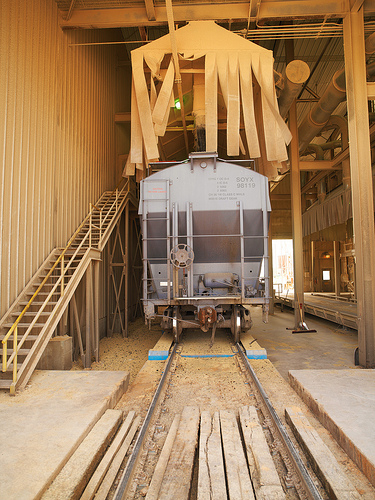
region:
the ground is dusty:
[27, 342, 120, 465]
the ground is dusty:
[8, 334, 160, 496]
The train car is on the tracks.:
[117, 150, 284, 355]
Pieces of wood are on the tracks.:
[64, 390, 336, 498]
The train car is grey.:
[126, 146, 288, 350]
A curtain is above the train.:
[109, 17, 300, 197]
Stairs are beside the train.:
[0, 174, 138, 399]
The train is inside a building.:
[0, 4, 374, 497]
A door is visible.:
[261, 225, 304, 319]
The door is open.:
[263, 232, 303, 317]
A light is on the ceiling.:
[163, 82, 197, 117]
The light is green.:
[160, 84, 193, 120]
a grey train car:
[133, 151, 274, 348]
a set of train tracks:
[99, 317, 343, 498]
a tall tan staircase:
[0, 173, 145, 396]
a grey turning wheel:
[167, 238, 195, 272]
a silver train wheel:
[227, 307, 242, 343]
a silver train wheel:
[170, 306, 180, 342]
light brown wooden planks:
[149, 403, 284, 497]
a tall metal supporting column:
[283, 98, 310, 336]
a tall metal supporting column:
[345, 12, 371, 369]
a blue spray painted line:
[144, 346, 266, 363]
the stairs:
[8, 150, 123, 393]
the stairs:
[11, 126, 165, 314]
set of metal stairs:
[0, 263, 74, 381]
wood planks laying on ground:
[174, 401, 284, 486]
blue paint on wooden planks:
[148, 345, 274, 366]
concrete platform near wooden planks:
[54, 388, 67, 426]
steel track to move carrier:
[212, 351, 281, 416]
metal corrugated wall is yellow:
[17, 50, 98, 149]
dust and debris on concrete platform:
[35, 369, 79, 422]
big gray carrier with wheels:
[139, 159, 263, 309]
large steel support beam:
[286, 107, 307, 350]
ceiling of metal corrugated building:
[295, 29, 349, 142]